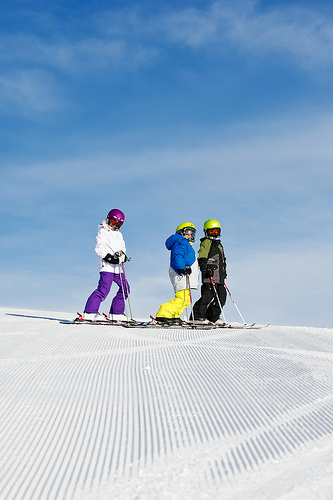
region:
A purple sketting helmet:
[99, 208, 128, 222]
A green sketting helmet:
[201, 219, 223, 227]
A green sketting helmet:
[171, 218, 200, 230]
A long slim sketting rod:
[115, 257, 128, 323]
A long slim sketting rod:
[186, 267, 196, 326]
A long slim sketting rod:
[211, 274, 225, 331]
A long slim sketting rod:
[223, 275, 255, 328]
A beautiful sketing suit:
[92, 208, 137, 324]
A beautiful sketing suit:
[164, 222, 195, 329]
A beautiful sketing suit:
[201, 213, 230, 331]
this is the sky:
[36, 42, 251, 159]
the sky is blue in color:
[118, 78, 183, 118]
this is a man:
[92, 212, 130, 295]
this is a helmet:
[106, 206, 127, 223]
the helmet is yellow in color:
[200, 217, 217, 226]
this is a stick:
[116, 266, 130, 313]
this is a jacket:
[178, 242, 187, 258]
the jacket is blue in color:
[174, 245, 185, 259]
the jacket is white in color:
[102, 232, 124, 244]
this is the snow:
[107, 358, 241, 432]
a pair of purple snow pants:
[84, 272, 129, 314]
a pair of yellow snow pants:
[152, 289, 190, 316]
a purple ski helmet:
[105, 208, 124, 230]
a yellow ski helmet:
[175, 223, 195, 238]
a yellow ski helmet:
[202, 220, 219, 231]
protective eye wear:
[204, 225, 221, 236]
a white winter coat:
[94, 220, 127, 271]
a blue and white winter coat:
[164, 234, 199, 289]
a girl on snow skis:
[59, 209, 152, 325]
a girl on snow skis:
[137, 221, 211, 325]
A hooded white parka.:
[93, 219, 127, 274]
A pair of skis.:
[117, 318, 223, 330]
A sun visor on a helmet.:
[206, 226, 218, 236]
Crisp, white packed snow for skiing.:
[0, 306, 330, 498]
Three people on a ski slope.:
[83, 208, 227, 324]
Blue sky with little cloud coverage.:
[1, 0, 331, 324]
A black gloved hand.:
[177, 266, 191, 275]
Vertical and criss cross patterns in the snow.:
[2, 329, 330, 498]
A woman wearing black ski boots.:
[153, 314, 180, 324]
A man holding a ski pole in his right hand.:
[209, 273, 229, 324]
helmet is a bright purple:
[107, 207, 119, 219]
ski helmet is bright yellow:
[168, 212, 195, 228]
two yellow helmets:
[171, 214, 218, 231]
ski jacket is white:
[94, 220, 140, 272]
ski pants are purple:
[94, 269, 120, 308]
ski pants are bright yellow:
[163, 285, 194, 317]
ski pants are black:
[202, 278, 229, 315]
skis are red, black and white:
[201, 271, 237, 312]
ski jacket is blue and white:
[171, 248, 197, 286]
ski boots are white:
[79, 309, 133, 321]